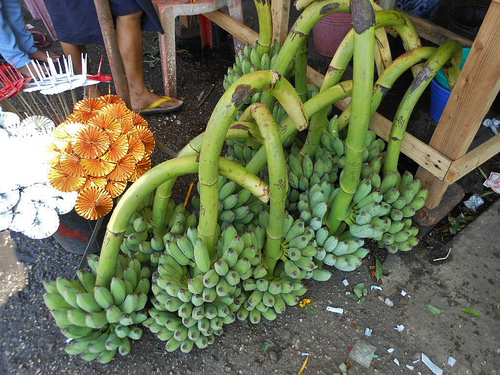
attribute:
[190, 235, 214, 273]
banana — green, unripened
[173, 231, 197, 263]
banana — green, unripened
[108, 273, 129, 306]
banana — green, unripened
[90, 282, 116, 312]
banana — green, unripened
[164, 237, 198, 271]
banana — green, unripened